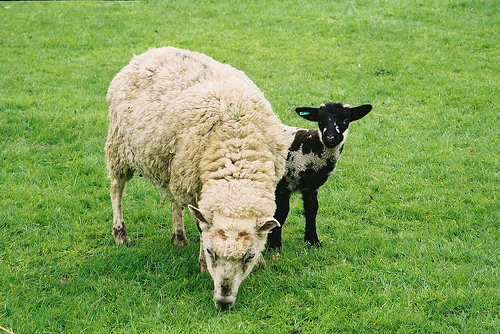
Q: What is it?
A: Lamb.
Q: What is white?
A: The lamb.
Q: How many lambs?
A: 2.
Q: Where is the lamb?
A: On the grass.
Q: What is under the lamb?
A: Baby.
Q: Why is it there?
A: To eat.